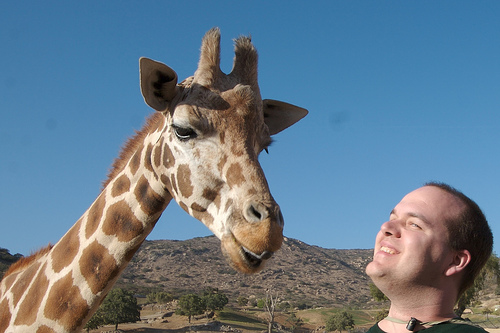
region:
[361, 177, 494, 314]
the head of a man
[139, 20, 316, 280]
the head of a girafffe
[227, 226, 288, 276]
the mouth of a giraffe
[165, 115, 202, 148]
the eye of a giraffe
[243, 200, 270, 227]
the nostril of a giraffe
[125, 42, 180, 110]
the ear of a giraffe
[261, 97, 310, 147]
the ear of a giraffe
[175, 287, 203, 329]
a tree in the photo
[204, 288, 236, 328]
a tree in the photo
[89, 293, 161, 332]
a tree in the photo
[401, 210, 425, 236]
the eye of a man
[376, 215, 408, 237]
the nose of a man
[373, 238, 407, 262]
the mouth of a man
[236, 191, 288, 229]
the nose of a giraffe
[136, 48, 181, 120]
the ear of a giraffe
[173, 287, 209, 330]
a small green tree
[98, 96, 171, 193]
the mane of a giraffe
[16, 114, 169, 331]
the neck of a giraffe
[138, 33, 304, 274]
this is the head of a giraffe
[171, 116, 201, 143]
this is the eye of a giraffe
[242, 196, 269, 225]
this is the nostril of a giraffe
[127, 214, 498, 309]
there is a hill in the picture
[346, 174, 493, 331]
this is a smiling man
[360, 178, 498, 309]
this is the head of a man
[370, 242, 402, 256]
this is the mouth of a man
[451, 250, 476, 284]
this is the ear of a man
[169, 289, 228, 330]
a tree with green leaves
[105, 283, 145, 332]
a tree with green leaves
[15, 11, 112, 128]
The sky is blue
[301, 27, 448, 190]
The sky is blue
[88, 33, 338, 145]
The giraffe has ears